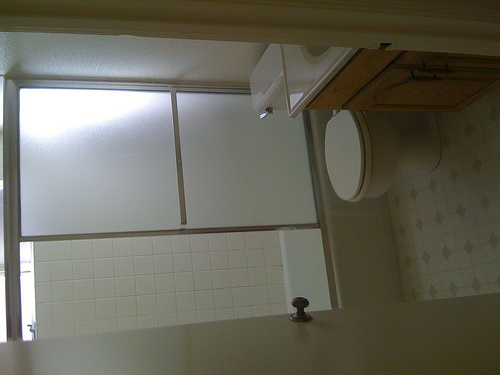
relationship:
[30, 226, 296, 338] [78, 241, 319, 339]
tile on wall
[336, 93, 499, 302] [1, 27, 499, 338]
flooring in bathroom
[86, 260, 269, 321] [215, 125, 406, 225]
white tile in bathroom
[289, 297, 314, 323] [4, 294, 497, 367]
handle in door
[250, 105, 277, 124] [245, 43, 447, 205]
handle in toilet